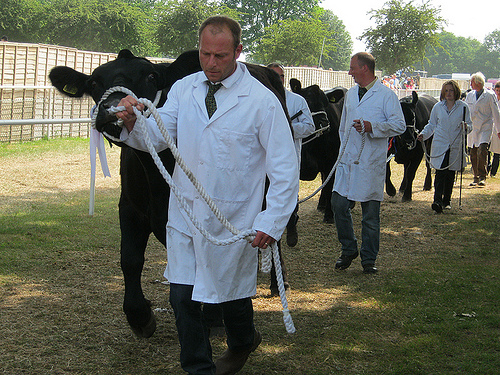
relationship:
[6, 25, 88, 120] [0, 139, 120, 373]
fence mounted in field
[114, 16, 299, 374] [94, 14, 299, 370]
man walking in field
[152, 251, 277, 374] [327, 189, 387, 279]
man walking in pants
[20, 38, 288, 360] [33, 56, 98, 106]
cow has ear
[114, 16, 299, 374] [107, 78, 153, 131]
man has hand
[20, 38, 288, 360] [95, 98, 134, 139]
cow has nose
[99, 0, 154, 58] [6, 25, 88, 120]
trees behind fence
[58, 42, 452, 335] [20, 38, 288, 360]
line of cows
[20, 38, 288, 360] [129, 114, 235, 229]
cow along rope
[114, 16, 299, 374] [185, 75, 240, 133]
man wearing tie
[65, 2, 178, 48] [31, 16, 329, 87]
trees in background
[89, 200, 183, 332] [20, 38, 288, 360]
leg of cow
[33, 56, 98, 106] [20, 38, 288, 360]
ear of cow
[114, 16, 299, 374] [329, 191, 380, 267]
man wearing pants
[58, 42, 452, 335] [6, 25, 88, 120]
people by fence